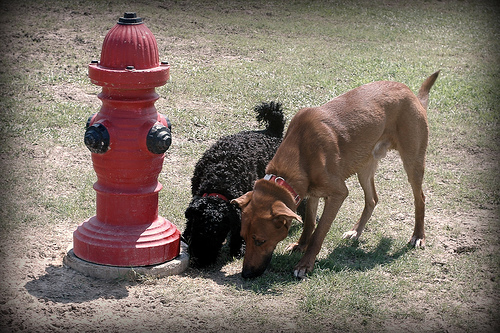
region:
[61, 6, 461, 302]
a fire hydrant with black and brown dogs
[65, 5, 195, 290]
a red and black water hydrant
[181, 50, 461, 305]
a black and brown dogs with red collar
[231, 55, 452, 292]
a brown dog with red collar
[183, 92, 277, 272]
a black dog with red collar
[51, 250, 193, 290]
a round cement base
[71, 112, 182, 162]
out cops of the fire hydrant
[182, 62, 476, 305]
two dogs sniffing the ground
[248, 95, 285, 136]
a black tail of a dog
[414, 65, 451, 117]
brown pointy tail of a dog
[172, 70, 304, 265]
this is a black dog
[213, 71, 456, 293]
this is a brown dog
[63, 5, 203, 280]
this is a red hydrant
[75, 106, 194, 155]
these are black knobs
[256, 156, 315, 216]
this is a collar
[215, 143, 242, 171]
this is curly fur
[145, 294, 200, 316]
this is brown dirt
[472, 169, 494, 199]
this is the grass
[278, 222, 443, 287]
these are dog paws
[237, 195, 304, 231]
these are dog ears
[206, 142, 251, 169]
Dog has black fur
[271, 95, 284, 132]
Dog has black tail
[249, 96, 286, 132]
Dogs tail is curled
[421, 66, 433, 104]
Dog has brown tail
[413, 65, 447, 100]
Dogs tail is pointy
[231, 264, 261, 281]
dog has black nose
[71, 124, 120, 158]
Black dial on fire hydrant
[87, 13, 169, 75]
top of fire hydrant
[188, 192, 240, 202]
Dog has red collar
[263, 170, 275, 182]
White patch on collar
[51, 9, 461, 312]
Two dogs next to a fire hydrant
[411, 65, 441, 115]
A brown dog's tail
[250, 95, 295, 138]
A black dog's tail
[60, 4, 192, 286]
A red and black fire hydrant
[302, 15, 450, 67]
A green grassy surface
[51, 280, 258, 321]
A dirt and grass surface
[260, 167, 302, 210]
A red and silver dog collar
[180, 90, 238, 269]
A black fuzzy dog with a red collar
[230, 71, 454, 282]
A brown dog with a red collar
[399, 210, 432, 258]
A dog's paw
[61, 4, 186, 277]
A red fire hydrant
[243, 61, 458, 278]
A medium sized brownish dog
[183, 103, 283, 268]
A small black dog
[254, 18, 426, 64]
Rough looking lawn in need of care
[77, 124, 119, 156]
Valve on fire hydrant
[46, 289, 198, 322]
Bare earth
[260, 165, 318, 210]
A reddish collar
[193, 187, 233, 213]
A reddish collar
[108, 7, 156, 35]
Top valve of fire hydrant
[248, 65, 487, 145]
Canine tails up in the air